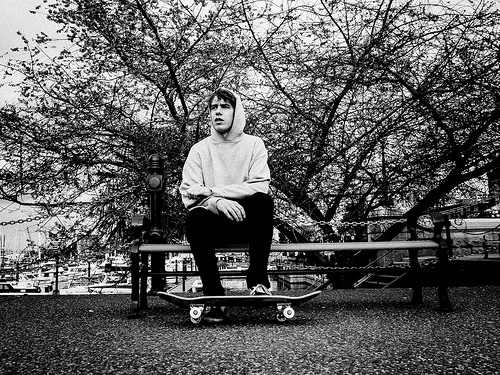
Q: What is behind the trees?
A: Boats.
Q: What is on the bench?
A: A man.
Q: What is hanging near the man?
A: A chain.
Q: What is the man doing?
A: Sitting.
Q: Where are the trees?
A: Behind the man.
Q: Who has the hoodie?
A: The man.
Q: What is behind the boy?
A: Trees.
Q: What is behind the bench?
A: Chains.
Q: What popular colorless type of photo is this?
A: Black and white.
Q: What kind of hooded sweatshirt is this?
A: Hoodie.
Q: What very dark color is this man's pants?
A: Black.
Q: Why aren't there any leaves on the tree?
A: Its cold.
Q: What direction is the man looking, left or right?
A: Left.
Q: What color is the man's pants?
A: Black.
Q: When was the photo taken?
A: Day time.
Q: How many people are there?
A: One.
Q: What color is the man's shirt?
A: Gray.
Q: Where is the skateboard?
A: The ground.